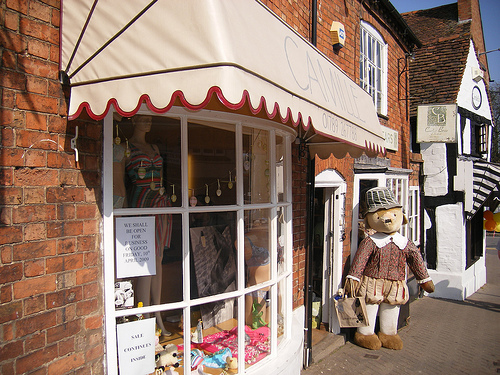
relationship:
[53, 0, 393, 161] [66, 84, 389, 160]
awning has trim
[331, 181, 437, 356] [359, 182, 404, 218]
teddy bear wears hat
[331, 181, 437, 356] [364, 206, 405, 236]
teddy bear has face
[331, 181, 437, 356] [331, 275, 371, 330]
teddy bear carries bag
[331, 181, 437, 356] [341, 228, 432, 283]
teddy bear wears jacket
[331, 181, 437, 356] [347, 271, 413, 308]
teddy bear wears slops [really]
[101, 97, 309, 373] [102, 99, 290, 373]
window has frame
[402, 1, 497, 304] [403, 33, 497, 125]
building has roof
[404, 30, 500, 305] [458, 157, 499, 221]
shop has awning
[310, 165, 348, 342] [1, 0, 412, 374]
doorway in building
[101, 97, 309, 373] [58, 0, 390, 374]
window of store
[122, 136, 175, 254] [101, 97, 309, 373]
dress in window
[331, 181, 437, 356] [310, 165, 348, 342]
teddy bear beside doorway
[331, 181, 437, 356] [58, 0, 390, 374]
teddy bear beside store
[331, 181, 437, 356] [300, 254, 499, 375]
teddy bear on sidewalk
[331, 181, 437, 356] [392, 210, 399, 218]
teddy bear has eye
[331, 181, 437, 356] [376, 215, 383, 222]
teddy bear has eye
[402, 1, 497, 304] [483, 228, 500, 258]
building adjacent to street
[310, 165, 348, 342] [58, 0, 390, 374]
doorway to store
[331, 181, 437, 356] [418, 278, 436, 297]
teddy bear has paw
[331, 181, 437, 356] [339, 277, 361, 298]
teddy bear has paw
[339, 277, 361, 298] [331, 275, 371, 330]
paw hold bag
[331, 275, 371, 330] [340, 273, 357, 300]
bag has handle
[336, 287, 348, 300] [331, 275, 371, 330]
toy in bag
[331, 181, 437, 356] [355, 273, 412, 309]
teddy bear wears slops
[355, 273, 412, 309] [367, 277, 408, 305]
slops reveal red thru slashes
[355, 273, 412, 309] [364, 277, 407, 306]
slops have red under-fabric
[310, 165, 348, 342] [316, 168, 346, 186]
doorway has arch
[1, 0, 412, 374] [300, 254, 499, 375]
building on sidewalk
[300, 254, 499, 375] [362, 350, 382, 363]
sidewalk has small drain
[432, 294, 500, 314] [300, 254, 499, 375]
shadow on sidewalk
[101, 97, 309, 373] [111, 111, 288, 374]
window has @ least 12 panes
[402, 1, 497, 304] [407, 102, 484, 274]
building has detailing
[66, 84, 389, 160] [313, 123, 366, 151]
trim has straight center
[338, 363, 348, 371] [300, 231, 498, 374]
spot on ground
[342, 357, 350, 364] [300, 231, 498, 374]
spot on ground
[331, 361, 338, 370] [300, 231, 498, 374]
spot on ground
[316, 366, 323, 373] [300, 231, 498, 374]
spot on ground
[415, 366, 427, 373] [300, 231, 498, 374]
spot on ground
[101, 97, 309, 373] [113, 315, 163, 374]
window has sign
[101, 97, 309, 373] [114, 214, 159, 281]
window has sign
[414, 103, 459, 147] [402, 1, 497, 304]
sign on building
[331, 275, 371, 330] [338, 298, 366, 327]
bag has logo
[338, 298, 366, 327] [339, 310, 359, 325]
logo has word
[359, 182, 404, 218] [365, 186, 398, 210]
hat has stripes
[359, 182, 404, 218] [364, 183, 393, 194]
hat has crown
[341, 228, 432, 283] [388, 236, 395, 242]
jacket has button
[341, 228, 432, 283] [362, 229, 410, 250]
jacket has collar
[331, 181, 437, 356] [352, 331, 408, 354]
teddy bear has feet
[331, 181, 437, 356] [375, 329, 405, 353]
teddy bear has foot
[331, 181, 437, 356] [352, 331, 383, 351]
teddy bear has feet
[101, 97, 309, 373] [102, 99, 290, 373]
window has merchandise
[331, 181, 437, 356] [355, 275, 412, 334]
teddy bear wears historic outfit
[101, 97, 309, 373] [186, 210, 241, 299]
window has pane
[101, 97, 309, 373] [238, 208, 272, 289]
window has pane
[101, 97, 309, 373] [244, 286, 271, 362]
window has pane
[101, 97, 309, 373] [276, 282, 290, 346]
window has pane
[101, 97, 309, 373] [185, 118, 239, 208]
window has pane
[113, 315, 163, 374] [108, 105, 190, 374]
sign on window's side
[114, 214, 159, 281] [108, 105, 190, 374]
sign on window's side